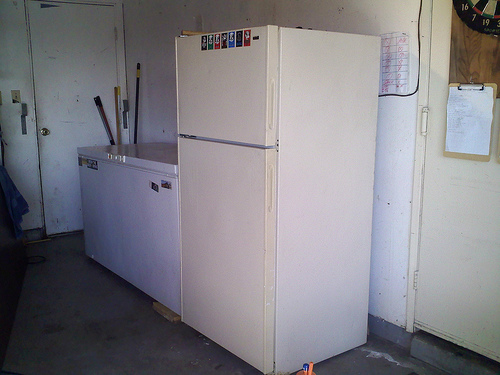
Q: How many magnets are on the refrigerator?
A: Seven.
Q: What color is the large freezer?
A: White.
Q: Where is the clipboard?
A: Hanging below the dartboard.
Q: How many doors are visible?
A: Two.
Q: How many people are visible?
A: None.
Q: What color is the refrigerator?
A: Off white / beige.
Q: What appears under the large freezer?
A: A block of wood.